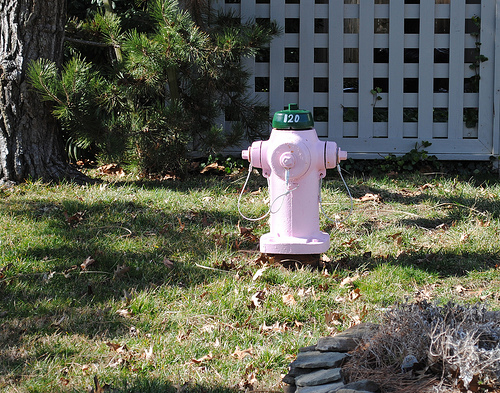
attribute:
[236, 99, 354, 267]
hydrant — pink, green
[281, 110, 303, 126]
120 — white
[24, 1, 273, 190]
bush — green, pine, small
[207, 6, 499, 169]
fence — wood, white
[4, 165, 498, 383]
grass — dry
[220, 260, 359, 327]
plants — dead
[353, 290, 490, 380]
plant — dead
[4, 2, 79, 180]
trunk — brown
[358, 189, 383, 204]
leaves — brown